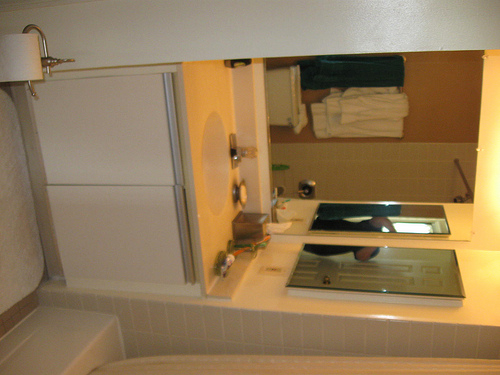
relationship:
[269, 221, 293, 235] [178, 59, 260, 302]
tissue on sink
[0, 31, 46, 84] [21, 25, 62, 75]
toilet paper in holder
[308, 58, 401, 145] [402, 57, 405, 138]
towels hanging on rod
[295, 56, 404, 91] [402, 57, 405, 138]
towel hanging on rod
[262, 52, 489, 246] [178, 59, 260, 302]
mirror above sink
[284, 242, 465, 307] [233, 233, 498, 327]
cabinet on wall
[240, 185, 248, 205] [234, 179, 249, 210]
soap in soap dish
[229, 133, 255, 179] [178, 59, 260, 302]
faucet above sink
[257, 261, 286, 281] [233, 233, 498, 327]
outlet on wall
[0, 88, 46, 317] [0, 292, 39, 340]
rug on floor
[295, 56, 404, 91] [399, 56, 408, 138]
towel on rack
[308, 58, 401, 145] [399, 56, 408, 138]
towels on rack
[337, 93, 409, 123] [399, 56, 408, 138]
towel on rack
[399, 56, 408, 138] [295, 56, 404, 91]
rack of towel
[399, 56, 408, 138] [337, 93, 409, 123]
rack of towel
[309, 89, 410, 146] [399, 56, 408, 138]
towels on rack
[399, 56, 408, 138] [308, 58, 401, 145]
rack of towels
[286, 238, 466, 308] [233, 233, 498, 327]
cabinet on wall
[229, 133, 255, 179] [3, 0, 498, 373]
faucet in bathroom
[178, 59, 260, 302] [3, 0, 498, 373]
sink in bathroom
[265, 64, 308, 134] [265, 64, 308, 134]
garbage can of garbage can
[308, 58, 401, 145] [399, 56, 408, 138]
towels hanging on rack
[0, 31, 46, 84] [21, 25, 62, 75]
toilet paper on holder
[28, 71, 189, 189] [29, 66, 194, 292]
door of cabinet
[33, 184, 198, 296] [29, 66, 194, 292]
door of cabinet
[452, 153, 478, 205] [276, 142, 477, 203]
shower curtain rod in shower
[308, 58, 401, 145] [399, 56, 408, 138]
towels hanging on towel rod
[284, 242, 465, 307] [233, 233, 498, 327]
cabinet hanging on wall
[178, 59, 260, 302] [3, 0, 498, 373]
sink of bathroom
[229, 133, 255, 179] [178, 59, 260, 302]
faucet of sink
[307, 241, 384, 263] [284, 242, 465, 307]
person in cabinet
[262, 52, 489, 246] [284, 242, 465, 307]
mirror next to cabinet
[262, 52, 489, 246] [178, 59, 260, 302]
mirror over sink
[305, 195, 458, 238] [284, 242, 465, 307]
reflection of cabinet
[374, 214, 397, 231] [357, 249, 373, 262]
reflection of arm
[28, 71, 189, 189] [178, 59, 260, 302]
door under sink